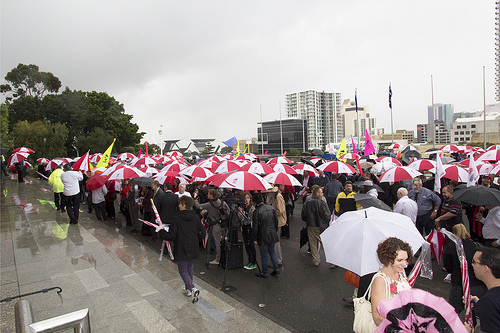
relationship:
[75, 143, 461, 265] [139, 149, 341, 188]
crowd with umbrellas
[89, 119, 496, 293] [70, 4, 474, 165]
people in weather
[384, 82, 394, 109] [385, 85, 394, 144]
flags on poles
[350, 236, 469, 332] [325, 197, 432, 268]
woman with umbrella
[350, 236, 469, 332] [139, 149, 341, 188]
woman with umbrellas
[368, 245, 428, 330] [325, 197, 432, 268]
woman with umbrella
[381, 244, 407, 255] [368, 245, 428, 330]
hair of woman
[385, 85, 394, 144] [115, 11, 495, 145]
poles in background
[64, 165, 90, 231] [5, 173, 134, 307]
man on sidewalk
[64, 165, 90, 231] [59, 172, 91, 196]
man wearing shirt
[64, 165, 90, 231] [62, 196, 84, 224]
man wearing pants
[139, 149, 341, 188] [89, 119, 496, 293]
umbrellas on people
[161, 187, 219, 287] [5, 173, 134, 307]
woman on sidewalk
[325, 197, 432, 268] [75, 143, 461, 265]
umbrella in crowd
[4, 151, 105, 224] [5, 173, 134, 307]
people on sidewalk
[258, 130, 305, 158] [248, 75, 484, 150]
building in town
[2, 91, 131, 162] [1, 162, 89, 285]
trees by road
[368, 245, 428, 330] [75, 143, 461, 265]
woman in crowd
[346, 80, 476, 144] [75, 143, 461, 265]
poles by crowd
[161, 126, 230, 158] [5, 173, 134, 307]
houses by sidewalk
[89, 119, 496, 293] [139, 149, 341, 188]
people under umbrellas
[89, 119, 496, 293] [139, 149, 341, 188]
people holding umbrellas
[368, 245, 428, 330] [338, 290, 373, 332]
woman carrying bag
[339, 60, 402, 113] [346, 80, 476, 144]
flags on poles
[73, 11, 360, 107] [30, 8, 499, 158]
clouds cover sky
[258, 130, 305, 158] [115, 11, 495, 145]
building in background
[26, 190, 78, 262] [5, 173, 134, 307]
reflections in sidewalk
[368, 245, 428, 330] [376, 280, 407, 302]
woman wearing top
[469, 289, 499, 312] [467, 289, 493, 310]
man wearing shirt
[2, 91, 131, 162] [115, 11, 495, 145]
trees in background